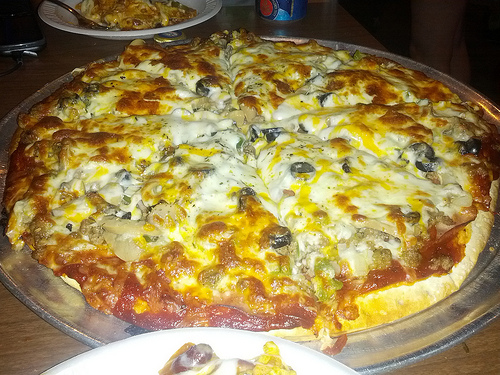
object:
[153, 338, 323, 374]
slice of pizza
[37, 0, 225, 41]
plate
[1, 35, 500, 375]
tray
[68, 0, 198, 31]
food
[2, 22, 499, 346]
pizza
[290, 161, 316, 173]
olive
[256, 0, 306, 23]
can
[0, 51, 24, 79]
wire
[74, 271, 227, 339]
crust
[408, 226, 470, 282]
sauce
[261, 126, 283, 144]
olives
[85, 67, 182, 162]
cheese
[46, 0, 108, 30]
fork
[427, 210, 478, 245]
sausage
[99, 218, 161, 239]
mushroom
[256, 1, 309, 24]
bottom part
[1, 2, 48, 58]
phone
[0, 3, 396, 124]
table